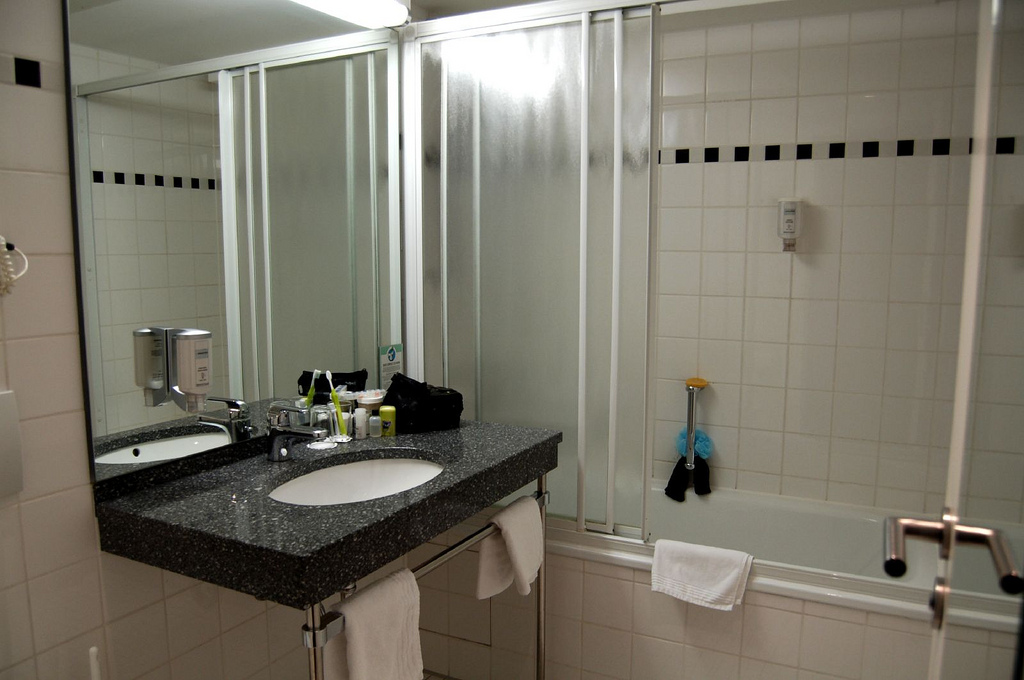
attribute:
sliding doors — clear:
[441, 6, 660, 542]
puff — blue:
[673, 427, 716, 465]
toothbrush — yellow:
[305, 361, 345, 403]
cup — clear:
[326, 398, 349, 438]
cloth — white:
[651, 535, 753, 611]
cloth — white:
[471, 494, 544, 603]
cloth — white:
[320, 555, 423, 676]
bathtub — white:
[667, 424, 870, 614]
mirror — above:
[52, 4, 403, 504]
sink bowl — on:
[263, 443, 447, 513]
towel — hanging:
[651, 460, 829, 673]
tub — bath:
[261, 414, 552, 655]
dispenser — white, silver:
[148, 319, 231, 419]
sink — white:
[264, 443, 443, 510]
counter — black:
[90, 389, 574, 625]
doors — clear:
[417, 25, 644, 540]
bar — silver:
[415, 543, 485, 585]